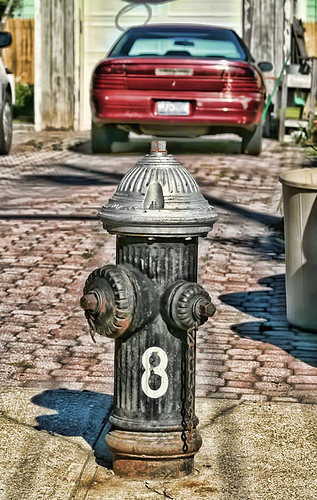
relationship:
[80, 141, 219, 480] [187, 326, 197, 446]
hydrant has a chain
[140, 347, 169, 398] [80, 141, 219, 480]
8 on hydrant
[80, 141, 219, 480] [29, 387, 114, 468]
hydrant has a shadow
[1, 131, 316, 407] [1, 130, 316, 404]
bricks on ground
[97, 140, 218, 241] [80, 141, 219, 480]
dome on hydrant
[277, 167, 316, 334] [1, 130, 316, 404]
trash can on ground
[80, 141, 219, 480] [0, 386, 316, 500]
hydrant on sidewalk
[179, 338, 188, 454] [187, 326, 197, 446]
shadow from chain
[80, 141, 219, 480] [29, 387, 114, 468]
hydrant making a shadow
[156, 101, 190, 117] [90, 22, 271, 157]
license plate on car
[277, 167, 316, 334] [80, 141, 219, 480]
trash can near hydrant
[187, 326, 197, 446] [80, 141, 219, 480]
chain on hydrant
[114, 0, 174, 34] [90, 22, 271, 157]
shadow in front of car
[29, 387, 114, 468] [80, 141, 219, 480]
shadow from hydrant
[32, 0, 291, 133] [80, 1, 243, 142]
garage has a door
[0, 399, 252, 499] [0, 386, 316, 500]
crack in sidewalk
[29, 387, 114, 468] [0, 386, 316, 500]
shadow on sidewalk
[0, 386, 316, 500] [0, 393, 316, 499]
sidewalk has stains